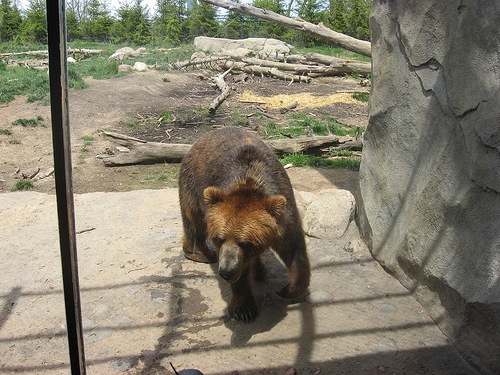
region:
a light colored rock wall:
[366, 10, 489, 340]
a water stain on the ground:
[136, 253, 228, 360]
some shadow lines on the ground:
[6, 263, 441, 373]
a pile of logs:
[173, 28, 363, 113]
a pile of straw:
[239, 89, 354, 112]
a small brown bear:
[176, 123, 313, 328]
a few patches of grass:
[69, 130, 96, 172]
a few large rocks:
[108, 43, 154, 75]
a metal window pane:
[42, 55, 87, 368]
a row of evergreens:
[41, 5, 362, 54]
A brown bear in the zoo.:
[164, 141, 298, 273]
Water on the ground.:
[144, 257, 220, 334]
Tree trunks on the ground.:
[222, 45, 366, 84]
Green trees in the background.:
[106, 7, 340, 39]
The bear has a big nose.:
[212, 235, 242, 282]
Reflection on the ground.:
[174, 274, 441, 361]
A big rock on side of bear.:
[296, 168, 351, 240]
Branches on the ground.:
[161, 41, 271, 95]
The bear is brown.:
[176, 100, 317, 291]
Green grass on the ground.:
[9, 60, 115, 90]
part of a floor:
[361, 254, 398, 294]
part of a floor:
[347, 298, 378, 345]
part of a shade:
[296, 308, 328, 359]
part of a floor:
[348, 288, 367, 315]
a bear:
[168, 137, 328, 329]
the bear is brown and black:
[178, 125, 322, 325]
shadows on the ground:
[309, 300, 387, 358]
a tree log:
[273, 9, 342, 41]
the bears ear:
[266, 193, 287, 223]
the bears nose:
[214, 259, 237, 281]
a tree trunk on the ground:
[113, 141, 158, 161]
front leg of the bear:
[285, 265, 311, 293]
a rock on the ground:
[308, 195, 355, 237]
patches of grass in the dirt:
[11, 118, 48, 129]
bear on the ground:
[154, 130, 348, 305]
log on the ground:
[109, 110, 349, 177]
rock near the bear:
[309, 181, 359, 239]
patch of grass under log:
[271, 102, 358, 172]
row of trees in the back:
[1, 3, 373, 42]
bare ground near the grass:
[74, 73, 166, 117]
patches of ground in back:
[3, 65, 120, 87]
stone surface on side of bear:
[359, 8, 499, 329]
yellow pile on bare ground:
[241, 85, 357, 108]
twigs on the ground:
[152, 108, 180, 141]